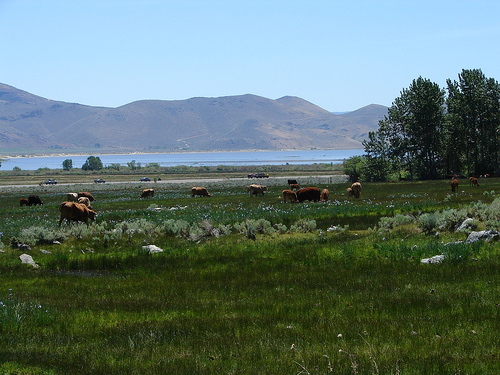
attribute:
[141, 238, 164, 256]
rock — white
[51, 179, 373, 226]
cows — grazing, grouped, brown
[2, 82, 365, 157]
hills — lined up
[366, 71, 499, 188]
trees — grouped, pine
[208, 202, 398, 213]
flowers — white, growing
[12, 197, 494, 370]
field — open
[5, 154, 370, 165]
lake — far, blue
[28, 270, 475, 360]
grass — tall, green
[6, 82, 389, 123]
mountains — far, distant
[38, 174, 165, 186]
cars — traveling, driving, lined up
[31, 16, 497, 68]
sky — clear, blue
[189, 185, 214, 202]
cow — alone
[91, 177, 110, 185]
car — blue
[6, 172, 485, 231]
cattle — grazing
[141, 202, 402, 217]
plants — white